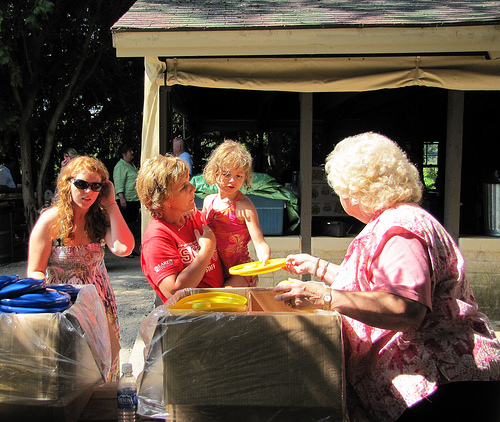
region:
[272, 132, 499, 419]
A woman in a pink shirt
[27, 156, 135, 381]
A red haired girl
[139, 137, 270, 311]
A woman carrying a child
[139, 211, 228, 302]
A red short sleeved shirt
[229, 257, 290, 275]
A yellow frisbee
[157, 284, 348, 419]
A card board box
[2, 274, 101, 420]
A box of blue frisbees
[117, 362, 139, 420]
A plastic bottle of water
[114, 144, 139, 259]
A woman in a green shirt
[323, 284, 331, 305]
A wrist watch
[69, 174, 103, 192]
sunglasses on a woman's face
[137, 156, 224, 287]
a woman holding a little girl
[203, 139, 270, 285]
a little girl in a woman's arms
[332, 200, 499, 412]
a flowery pink shirt on a woman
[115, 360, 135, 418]
a plastic water bottle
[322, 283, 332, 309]
a watch on a woman's wrist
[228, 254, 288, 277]
a yellow plate in a woman's hand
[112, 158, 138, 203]
a green shirt on a woman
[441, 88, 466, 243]
a wooden post behind a woman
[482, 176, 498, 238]
a metal trash can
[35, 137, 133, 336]
a woman talking on the phone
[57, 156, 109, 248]
the head of a woman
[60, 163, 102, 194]
the sunglasses of a woman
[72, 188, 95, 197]
the nose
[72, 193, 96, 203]
the mouth of a woman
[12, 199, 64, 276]
the right arm of a woman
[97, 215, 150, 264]
the left arm of a woman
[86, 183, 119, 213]
the left hand of a woman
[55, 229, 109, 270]
the dress of a woman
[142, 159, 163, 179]
the hair of a woman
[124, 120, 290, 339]
woman holding a little girl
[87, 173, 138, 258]
hand lifted up to the face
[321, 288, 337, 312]
watch around the wrist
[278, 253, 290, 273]
fingers around the edge of the plate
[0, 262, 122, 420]
blue plates in a box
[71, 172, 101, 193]
sunglasses on the face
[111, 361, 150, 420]
clear plastic water bottle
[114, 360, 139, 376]
white cap on top of the bottle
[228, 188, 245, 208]
pink strap around the shoulder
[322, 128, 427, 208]
curly white hair on the head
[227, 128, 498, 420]
Woman passing a frisbee to a girl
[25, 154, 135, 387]
Woman tucking her hair behind her ear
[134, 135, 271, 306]
Woman holding a girl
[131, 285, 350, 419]
Cardboard box wrapped in plastic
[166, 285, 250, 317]
Yellow frisbees in a cardboard box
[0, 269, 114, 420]
Box full of blue frisbees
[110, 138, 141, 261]
Woman in a green shirt and black pants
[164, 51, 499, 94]
Rolled up canopy wall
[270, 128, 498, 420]
Woman wearing a pink shirt and black pants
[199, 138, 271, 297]
Child receiving a frisbee from a woman